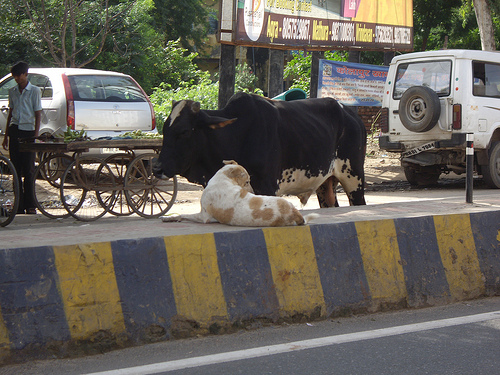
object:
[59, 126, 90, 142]
vegetable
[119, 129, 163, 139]
vegetable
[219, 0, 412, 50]
billboard advertisement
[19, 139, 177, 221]
bike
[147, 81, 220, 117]
bushes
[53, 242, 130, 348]
stripe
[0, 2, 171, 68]
trees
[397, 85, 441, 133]
tire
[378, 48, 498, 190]
jeep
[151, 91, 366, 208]
cow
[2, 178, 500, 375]
sidewalk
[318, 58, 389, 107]
sign